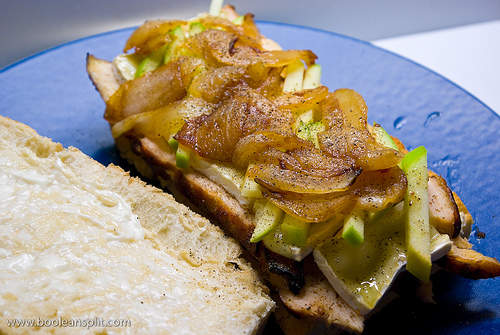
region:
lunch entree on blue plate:
[23, 11, 473, 320]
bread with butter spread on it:
[9, 98, 261, 328]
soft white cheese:
[304, 221, 460, 315]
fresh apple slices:
[398, 145, 442, 291]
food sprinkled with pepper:
[156, 32, 440, 249]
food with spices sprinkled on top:
[159, 36, 406, 261]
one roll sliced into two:
[27, 33, 477, 310]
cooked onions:
[156, 36, 415, 225]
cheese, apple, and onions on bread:
[116, 38, 449, 315]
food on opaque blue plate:
[28, 30, 488, 305]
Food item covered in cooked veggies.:
[72, 13, 479, 265]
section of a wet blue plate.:
[381, 96, 425, 122]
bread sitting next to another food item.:
[44, 228, 166, 298]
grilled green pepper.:
[403, 154, 432, 284]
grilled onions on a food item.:
[239, 119, 303, 154]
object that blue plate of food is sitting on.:
[419, 40, 473, 65]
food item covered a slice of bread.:
[97, 269, 151, 311]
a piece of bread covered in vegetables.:
[67, 64, 155, 125]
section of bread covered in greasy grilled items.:
[269, 261, 371, 324]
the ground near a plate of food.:
[17, 19, 61, 34]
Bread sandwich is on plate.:
[16, 55, 448, 334]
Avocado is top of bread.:
[253, 213, 374, 249]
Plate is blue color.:
[372, 67, 472, 158]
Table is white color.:
[431, 33, 498, 78]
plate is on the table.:
[379, 33, 496, 134]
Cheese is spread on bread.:
[15, 213, 175, 313]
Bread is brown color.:
[139, 194, 221, 270]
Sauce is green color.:
[331, 246, 390, 288]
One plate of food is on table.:
[17, 58, 468, 325]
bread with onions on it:
[106, 19, 498, 256]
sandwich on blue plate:
[16, 27, 357, 329]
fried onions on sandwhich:
[104, 14, 491, 311]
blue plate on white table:
[64, 31, 494, 326]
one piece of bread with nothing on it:
[3, 56, 300, 330]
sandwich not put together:
[50, 11, 381, 333]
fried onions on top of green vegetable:
[101, 7, 413, 268]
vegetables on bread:
[121, 14, 409, 276]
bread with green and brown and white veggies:
[24, 23, 464, 302]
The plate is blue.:
[14, 15, 490, 329]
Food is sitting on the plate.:
[56, 30, 489, 313]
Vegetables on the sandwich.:
[107, 44, 435, 292]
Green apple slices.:
[387, 108, 444, 291]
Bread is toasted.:
[1, 105, 269, 331]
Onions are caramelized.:
[115, 32, 380, 223]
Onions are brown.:
[198, 82, 398, 197]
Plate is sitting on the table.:
[10, 9, 497, 303]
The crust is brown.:
[7, 103, 277, 326]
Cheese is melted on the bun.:
[5, 142, 248, 326]